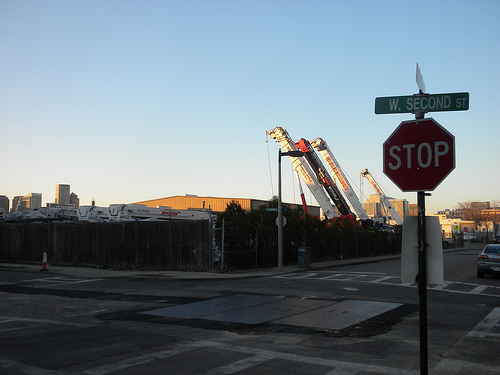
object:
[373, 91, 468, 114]
sign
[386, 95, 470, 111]
w. second st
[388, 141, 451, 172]
lettering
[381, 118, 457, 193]
sign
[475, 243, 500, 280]
toyota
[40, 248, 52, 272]
cone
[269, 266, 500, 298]
crosswalk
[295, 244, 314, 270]
can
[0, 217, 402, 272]
fence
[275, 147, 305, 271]
streetlight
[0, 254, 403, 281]
sidewalk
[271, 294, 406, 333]
hole covers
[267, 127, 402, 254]
cranes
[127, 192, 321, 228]
building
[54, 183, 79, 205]
buildings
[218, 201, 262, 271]
shrubs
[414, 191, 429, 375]
post